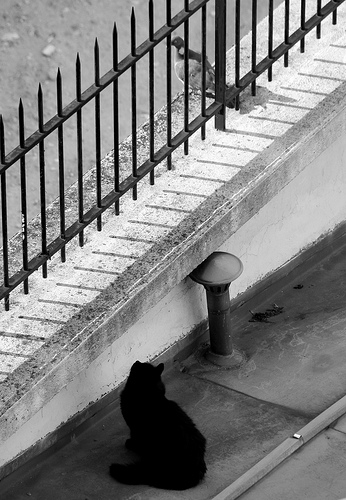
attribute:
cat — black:
[109, 357, 207, 490]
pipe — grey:
[187, 250, 244, 365]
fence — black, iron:
[14, 22, 315, 274]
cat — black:
[86, 352, 236, 469]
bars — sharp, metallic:
[2, 0, 345, 311]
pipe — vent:
[191, 248, 243, 367]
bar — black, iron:
[214, 0, 226, 131]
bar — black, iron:
[182, 0, 189, 155]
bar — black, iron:
[129, 7, 137, 200]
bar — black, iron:
[93, 38, 101, 231]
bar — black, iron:
[18, 97, 29, 294]